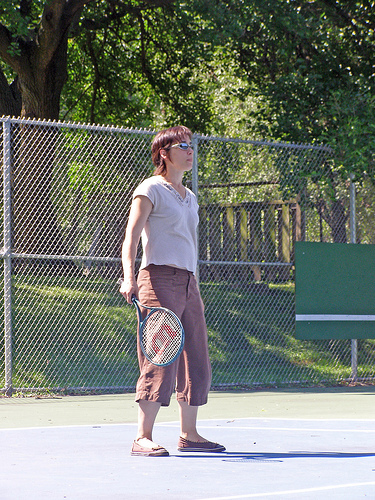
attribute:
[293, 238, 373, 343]
green board — attached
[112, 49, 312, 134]
tree — leafy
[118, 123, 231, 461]
woman — wearing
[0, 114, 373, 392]
fence — chain link, silver, metal, Wire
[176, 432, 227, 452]
sneaker — flat brown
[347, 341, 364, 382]
pole — metal, supporting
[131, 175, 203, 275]
shirt — white, vneck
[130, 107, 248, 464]
woman — standing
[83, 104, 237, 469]
girl — holding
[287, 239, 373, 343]
scoreboard — blank green, unused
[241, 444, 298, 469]
shade — Dark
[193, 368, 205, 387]
short — Brown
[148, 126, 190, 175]
hair — short, reddish brown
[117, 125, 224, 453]
player — female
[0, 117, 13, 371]
post — straight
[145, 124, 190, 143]
hair — short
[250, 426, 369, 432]
lines — white